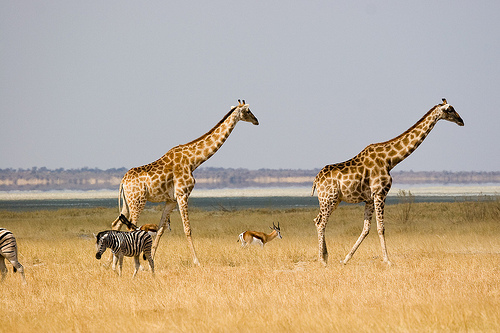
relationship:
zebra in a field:
[87, 222, 168, 280] [81, 197, 381, 309]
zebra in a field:
[78, 207, 167, 287] [1, 182, 385, 319]